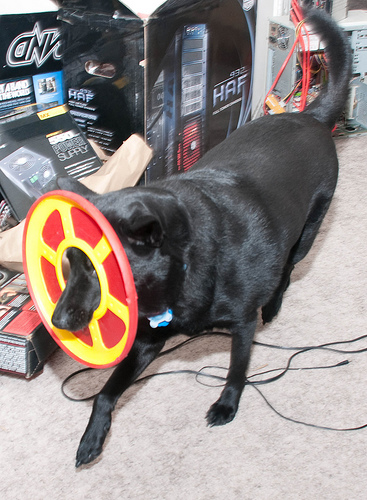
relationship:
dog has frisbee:
[121, 159, 296, 277] [33, 204, 136, 277]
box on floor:
[8, 308, 37, 371] [10, 376, 51, 463]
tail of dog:
[315, 17, 346, 107] [121, 159, 296, 277]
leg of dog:
[207, 316, 248, 439] [121, 159, 296, 277]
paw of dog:
[207, 396, 228, 420] [121, 159, 296, 277]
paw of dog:
[70, 418, 117, 451] [121, 159, 296, 277]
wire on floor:
[302, 343, 338, 457] [10, 376, 51, 463]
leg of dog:
[90, 336, 160, 456] [121, 159, 296, 277]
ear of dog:
[132, 211, 161, 247] [121, 159, 296, 277]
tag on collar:
[156, 313, 188, 329] [182, 247, 190, 281]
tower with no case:
[282, 10, 358, 92] [347, 32, 365, 74]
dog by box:
[121, 159, 296, 277] [8, 308, 37, 371]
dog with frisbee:
[121, 159, 296, 277] [33, 204, 136, 277]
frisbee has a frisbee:
[33, 204, 136, 277] [20, 189, 138, 371]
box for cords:
[278, 11, 315, 82] [287, 52, 315, 122]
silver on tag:
[158, 314, 174, 335] [156, 313, 188, 329]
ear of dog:
[56, 181, 92, 198] [121, 159, 296, 277]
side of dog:
[210, 168, 307, 308] [121, 159, 296, 277]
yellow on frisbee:
[29, 214, 37, 253] [33, 204, 136, 277]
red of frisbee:
[72, 195, 102, 223] [33, 204, 136, 277]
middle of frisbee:
[58, 252, 76, 281] [33, 204, 136, 277]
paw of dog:
[266, 301, 279, 326] [121, 159, 296, 277]